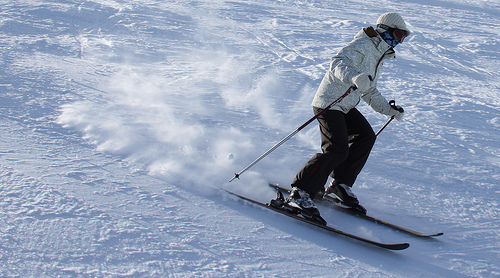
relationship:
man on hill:
[216, 19, 496, 244] [70, 76, 458, 268]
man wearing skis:
[282, 11, 411, 220] [220, 178, 443, 249]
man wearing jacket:
[282, 11, 411, 220] [281, 20, 409, 123]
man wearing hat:
[282, 11, 411, 220] [373, 9, 411, 33]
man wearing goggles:
[282, 11, 411, 220] [374, 20, 409, 45]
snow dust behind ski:
[41, 20, 295, 220] [288, 6, 416, 227]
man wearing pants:
[282, 11, 411, 220] [291, 104, 376, 197]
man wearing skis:
[282, 11, 411, 220] [248, 176, 428, 251]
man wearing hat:
[282, 11, 411, 220] [375, 6, 416, 36]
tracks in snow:
[11, 1, 324, 207] [2, 1, 485, 276]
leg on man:
[298, 113, 349, 197] [282, 11, 411, 220]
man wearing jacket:
[282, 11, 411, 220] [304, 16, 404, 125]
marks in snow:
[241, 22, 318, 76] [2, 1, 485, 276]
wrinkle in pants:
[296, 167, 306, 180] [290, 104, 378, 186]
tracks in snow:
[11, 6, 280, 206] [2, 1, 485, 276]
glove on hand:
[341, 64, 385, 109] [345, 69, 377, 99]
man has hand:
[282, 11, 411, 220] [345, 69, 377, 99]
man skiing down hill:
[282, 11, 411, 220] [0, 8, 497, 275]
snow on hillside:
[61, 157, 141, 274] [9, 2, 472, 270]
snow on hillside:
[0, 0, 500, 278] [9, 2, 472, 270]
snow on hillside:
[0, 0, 500, 278] [13, 167, 498, 277]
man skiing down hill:
[282, 11, 411, 220] [3, 109, 496, 275]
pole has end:
[227, 73, 374, 185] [224, 181, 256, 213]